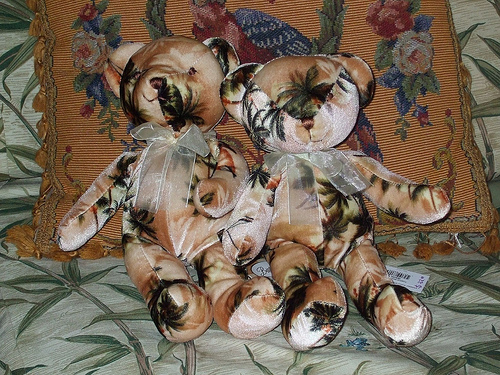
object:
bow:
[131, 123, 211, 221]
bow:
[259, 150, 366, 226]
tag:
[385, 262, 431, 297]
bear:
[220, 54, 450, 351]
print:
[227, 70, 332, 148]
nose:
[296, 115, 325, 134]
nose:
[147, 72, 171, 94]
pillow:
[9, 1, 498, 262]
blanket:
[1, 2, 488, 373]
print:
[3, 261, 157, 373]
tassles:
[12, 1, 55, 247]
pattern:
[358, 4, 464, 135]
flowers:
[363, 2, 420, 35]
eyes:
[128, 65, 145, 82]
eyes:
[261, 90, 284, 112]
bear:
[59, 37, 288, 341]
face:
[225, 55, 375, 152]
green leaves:
[436, 258, 499, 328]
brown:
[74, 286, 149, 373]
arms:
[193, 136, 254, 218]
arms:
[59, 140, 142, 251]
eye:
[188, 67, 200, 77]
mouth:
[283, 129, 335, 152]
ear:
[103, 38, 144, 100]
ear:
[204, 35, 244, 79]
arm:
[344, 144, 450, 227]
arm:
[221, 162, 276, 266]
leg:
[343, 247, 433, 351]